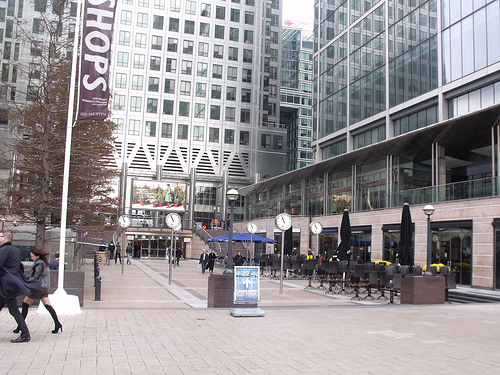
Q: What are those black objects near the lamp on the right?
A: Umbrellas.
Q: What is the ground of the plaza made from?
A: Bricks.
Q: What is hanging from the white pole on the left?
A: A banner.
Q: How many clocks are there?
A: Five.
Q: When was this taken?
A: During the day.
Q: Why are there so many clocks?
A: They tell the time in different cities.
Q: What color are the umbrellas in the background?
A: Blue.